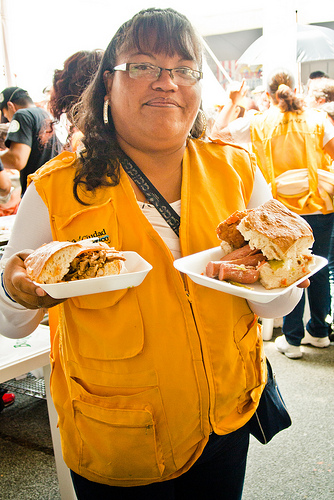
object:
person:
[1, 1, 321, 498]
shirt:
[24, 133, 261, 482]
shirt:
[4, 107, 63, 203]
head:
[98, 9, 202, 152]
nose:
[150, 70, 179, 93]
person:
[302, 73, 334, 128]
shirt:
[253, 104, 333, 219]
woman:
[1, 4, 306, 500]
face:
[104, 25, 203, 148]